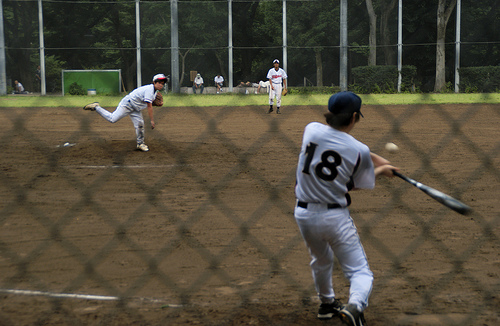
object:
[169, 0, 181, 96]
pole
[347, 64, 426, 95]
bush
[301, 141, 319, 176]
number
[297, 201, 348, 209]
belt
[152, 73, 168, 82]
baseball cap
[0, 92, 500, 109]
grass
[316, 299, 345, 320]
shoe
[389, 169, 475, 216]
bat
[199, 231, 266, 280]
dirt patch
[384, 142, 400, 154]
baseball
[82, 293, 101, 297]
part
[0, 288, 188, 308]
line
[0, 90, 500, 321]
baseball field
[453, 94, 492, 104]
grass patch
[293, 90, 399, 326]
baseball player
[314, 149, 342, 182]
number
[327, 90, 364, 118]
cap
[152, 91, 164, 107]
catching mitt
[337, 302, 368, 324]
shoe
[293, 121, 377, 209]
shirt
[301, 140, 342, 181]
number eighteen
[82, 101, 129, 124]
leg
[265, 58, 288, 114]
baseball player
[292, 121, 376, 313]
uniform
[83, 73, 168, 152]
baseball player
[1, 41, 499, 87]
fence